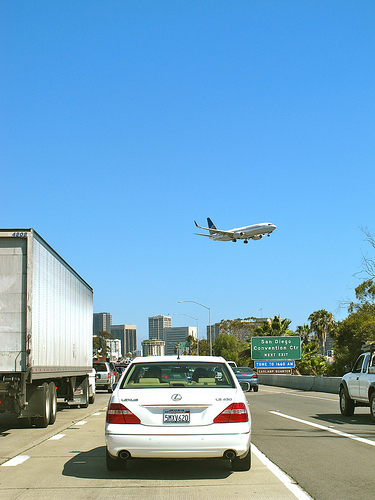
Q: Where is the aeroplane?
A: Flying in the sky.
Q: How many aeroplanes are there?
A: One.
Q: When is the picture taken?
A: Daytime.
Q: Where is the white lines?
A: In the road.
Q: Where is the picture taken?
A: On a highway.